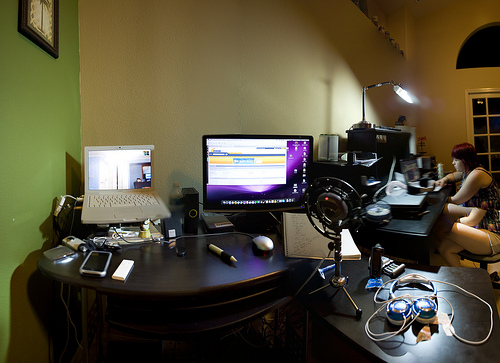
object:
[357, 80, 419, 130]
lamp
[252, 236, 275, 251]
computer mouse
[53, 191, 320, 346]
desk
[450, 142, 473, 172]
head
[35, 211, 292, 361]
table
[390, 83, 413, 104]
light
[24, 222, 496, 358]
desk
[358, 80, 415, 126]
light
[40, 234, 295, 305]
table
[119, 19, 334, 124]
wall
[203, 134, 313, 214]
monitor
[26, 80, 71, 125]
green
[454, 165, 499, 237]
strap top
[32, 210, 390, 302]
desk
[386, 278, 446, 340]
headphones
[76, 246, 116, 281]
smartphone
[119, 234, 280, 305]
desk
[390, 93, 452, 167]
ground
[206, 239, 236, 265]
pen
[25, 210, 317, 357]
table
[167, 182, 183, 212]
bottle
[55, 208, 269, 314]
desk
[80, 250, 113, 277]
cellphone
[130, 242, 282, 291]
table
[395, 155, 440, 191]
loptop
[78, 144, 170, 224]
laptop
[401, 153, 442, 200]
laptop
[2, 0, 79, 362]
wall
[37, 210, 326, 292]
table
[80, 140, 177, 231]
laptop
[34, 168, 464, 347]
desk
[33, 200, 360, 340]
table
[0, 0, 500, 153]
background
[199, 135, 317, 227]
monitor